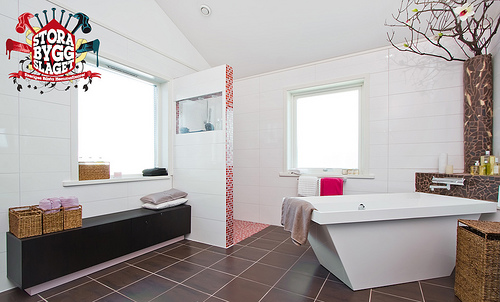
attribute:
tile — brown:
[155, 259, 202, 283]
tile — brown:
[180, 267, 235, 295]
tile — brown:
[207, 255, 253, 277]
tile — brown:
[235, 262, 289, 286]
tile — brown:
[212, 276, 272, 300]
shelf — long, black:
[5, 202, 192, 289]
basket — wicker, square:
[7, 205, 41, 239]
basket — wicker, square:
[41, 200, 60, 235]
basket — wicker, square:
[61, 203, 85, 230]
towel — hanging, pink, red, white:
[319, 175, 346, 197]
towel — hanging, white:
[298, 172, 320, 195]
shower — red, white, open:
[171, 64, 270, 248]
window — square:
[173, 91, 222, 134]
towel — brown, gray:
[280, 196, 316, 248]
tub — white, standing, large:
[298, 189, 498, 290]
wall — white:
[232, 26, 499, 227]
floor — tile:
[0, 226, 458, 300]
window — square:
[283, 77, 366, 175]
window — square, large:
[73, 54, 167, 180]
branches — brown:
[383, 1, 498, 63]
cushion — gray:
[140, 186, 187, 205]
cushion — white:
[141, 199, 187, 211]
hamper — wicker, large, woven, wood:
[453, 218, 499, 301]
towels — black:
[142, 167, 168, 179]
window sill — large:
[60, 173, 168, 189]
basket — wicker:
[78, 162, 111, 180]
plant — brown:
[382, 0, 498, 175]